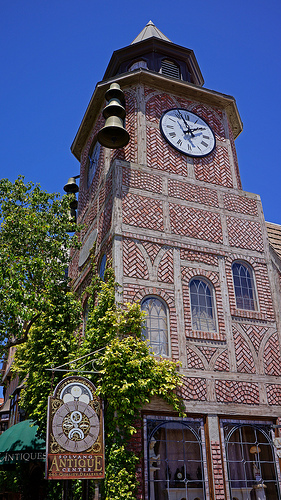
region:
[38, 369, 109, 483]
brown antique sign on a pole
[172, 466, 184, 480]
clock in the window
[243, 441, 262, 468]
lamp in the window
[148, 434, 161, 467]
statue in the window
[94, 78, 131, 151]
three bells on the building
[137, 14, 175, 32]
roof of the tower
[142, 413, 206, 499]
window on the building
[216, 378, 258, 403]
design on the building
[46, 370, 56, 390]
chain that is holding the sign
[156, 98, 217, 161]
clock on the tower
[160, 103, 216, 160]
white round clock face on brick tower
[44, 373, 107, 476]
brown sign with clock face advertising antique store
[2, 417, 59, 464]
green fabric awning advertising antiques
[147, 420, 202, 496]
semi circle shaped paned glass windows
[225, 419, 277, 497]
semi circle shaped glass window with panes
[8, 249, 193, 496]
lush green ivy climbing up building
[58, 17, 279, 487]
brick tower designed with gothic arches and pointed turret at top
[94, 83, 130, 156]
three metal bells hanging from tower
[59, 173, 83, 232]
three metal bells hanging from tower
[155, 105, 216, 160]
clock reads 1:55pm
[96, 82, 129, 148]
metal bells hanging from building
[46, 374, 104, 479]
sign for Solvang Antique Center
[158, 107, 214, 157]
large outdoor clock on wall of tower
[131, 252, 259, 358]
set of three windows in exterior wall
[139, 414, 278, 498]
ground floor windows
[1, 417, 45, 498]
entryway to antique center in Solvang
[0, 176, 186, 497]
trees on sidewalk in downtown Solvant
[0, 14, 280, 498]
Scandinavian-influenced building in Solvang, California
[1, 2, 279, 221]
dark blue California sky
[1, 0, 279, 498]
sunny day under blue skies in Solvang, California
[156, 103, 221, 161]
A clock on a building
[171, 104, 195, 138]
The clock's hour hand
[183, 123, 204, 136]
The clock's hour hand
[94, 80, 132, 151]
Three bells on the left side of the building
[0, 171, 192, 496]
A tree with green leaves next to the building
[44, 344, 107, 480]
An antique store sign in front of the bulding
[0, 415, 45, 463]
A green awning in front of the antique store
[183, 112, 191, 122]
The number 12 on the clock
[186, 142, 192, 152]
The number six on the clock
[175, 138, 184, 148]
the number seven on the clock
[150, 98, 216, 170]
clock on red tower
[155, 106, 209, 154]
clock has white face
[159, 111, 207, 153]
clock has roman numerals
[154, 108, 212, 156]
roman numerals are black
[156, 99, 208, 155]
clock has black hands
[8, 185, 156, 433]
green and leafy tree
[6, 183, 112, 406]
tree is next to building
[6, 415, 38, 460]
green awning near sign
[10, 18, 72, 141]
sky is blue and clear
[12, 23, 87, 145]
no clouds in sky